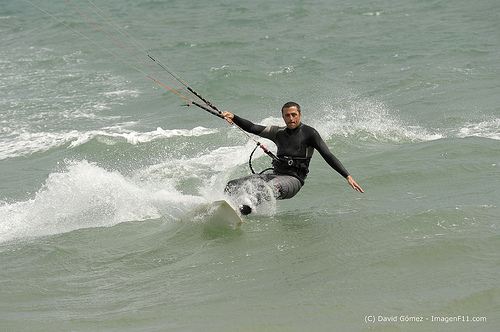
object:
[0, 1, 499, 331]
water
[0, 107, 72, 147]
wave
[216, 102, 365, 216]
man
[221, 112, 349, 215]
wet suit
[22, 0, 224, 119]
wire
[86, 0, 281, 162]
set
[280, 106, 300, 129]
face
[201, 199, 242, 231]
board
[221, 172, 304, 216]
bottom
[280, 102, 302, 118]
hair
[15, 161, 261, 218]
wake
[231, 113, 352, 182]
shirt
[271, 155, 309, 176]
belt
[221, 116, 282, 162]
wire